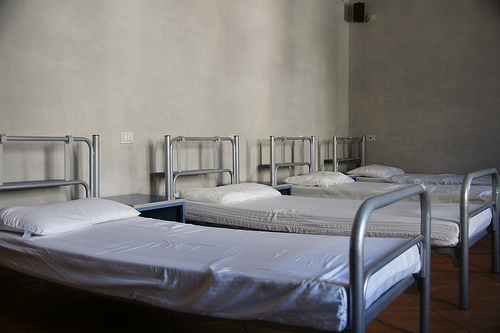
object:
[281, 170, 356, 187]
pillow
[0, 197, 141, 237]
pillow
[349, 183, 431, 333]
iron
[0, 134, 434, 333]
beds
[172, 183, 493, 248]
mattresses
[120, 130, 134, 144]
light switch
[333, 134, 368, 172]
head board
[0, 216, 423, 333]
sheets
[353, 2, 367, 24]
equipment piece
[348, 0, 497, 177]
wall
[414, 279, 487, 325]
floor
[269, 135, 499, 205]
bed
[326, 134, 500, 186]
bed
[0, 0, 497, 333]
room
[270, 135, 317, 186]
head board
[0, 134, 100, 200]
head board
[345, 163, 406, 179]
pillow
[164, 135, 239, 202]
board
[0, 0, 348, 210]
wall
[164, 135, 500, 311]
beds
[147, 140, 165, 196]
shadows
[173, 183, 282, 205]
pillow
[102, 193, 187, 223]
table